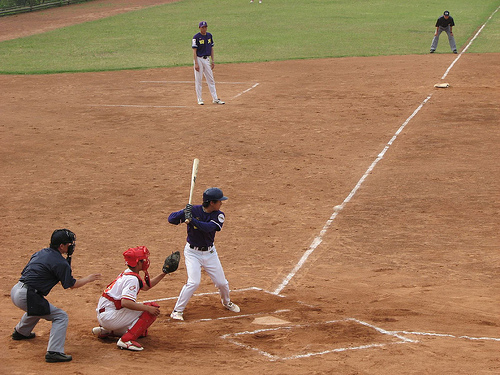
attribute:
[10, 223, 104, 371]
catcher — waiting, preparing, holding, equipped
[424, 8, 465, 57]
umpire — standing, calling, waiting, watching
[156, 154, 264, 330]
batter — standing, batting, ready, playing, holding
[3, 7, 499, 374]
field — dirty, brown, grassy, lined, dirt, brownish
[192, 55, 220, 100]
pants — white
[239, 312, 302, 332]
plate — brown, dirty, marked, white, dirt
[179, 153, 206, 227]
bat — wooden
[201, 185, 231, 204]
helmet — blue